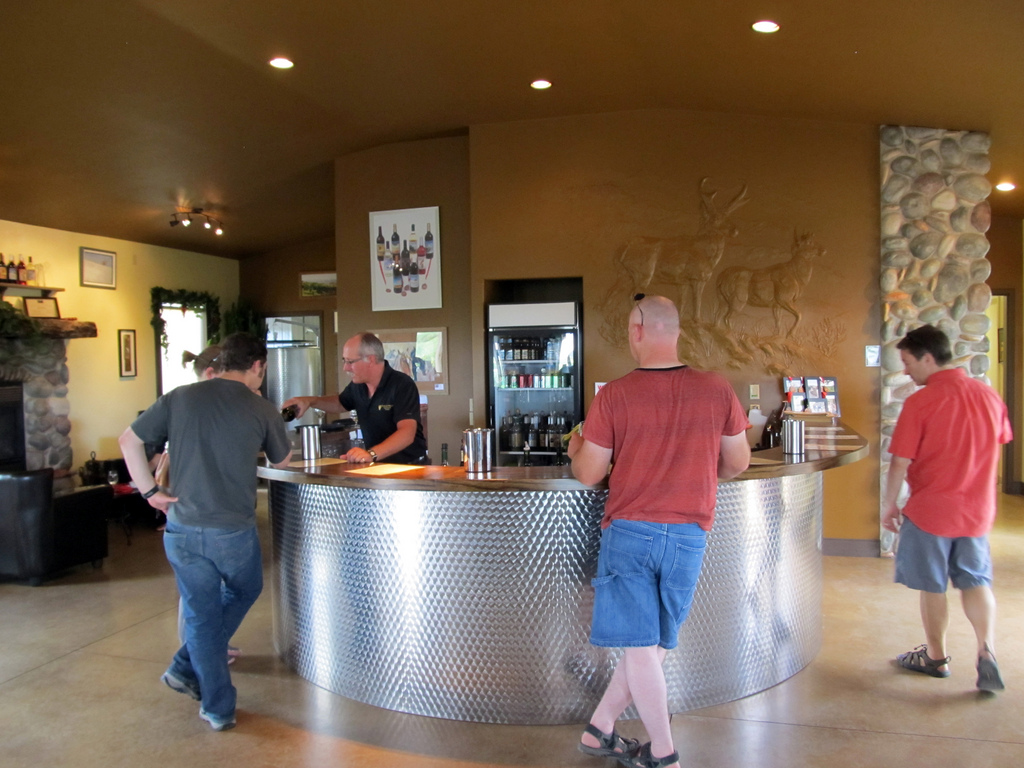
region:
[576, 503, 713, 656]
Man wearing shorts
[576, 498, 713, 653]
Man is wearing shorts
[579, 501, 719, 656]
Man wearing blue shorts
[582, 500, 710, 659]
Man wearing jean shorts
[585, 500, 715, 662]
Man is wearing jean shorts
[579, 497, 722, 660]
Man wearing blue jean shorts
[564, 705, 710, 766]
Man wearing sandals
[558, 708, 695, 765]
Man is wearing sandals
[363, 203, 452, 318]
framed artwork on a wall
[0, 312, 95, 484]
stone and mortar fireplace with wooden mantel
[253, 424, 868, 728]
horseshoe shaped metal bar with wooden counter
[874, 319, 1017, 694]
man wearing sandals, shorts and a shortsleeved red shirt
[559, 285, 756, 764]
man with sunglasses on his head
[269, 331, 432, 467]
bartender with glasses pouring a drink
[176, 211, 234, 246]
ceiling lighting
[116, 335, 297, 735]
man wearing sneakers, jeans and a short sleeved tee shirt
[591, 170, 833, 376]
frieze of deer on a wall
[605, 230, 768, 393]
the head of a man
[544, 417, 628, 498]
the elbow of a man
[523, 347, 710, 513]
the arm of a man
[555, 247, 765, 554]
the back of a man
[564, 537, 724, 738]
the legs of a man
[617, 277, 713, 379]
the hair of a man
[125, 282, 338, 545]
a man wearing a shirt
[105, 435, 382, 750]
a man wearing pants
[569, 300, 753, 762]
A bald man standing at a desk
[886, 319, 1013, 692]
A man in a red shirt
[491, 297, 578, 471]
A beverage refrigerated container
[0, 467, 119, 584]
A black chair by the fireplace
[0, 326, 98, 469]
A stone brick fireplace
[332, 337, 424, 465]
The bartender behind the bar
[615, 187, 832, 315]
A deer drawing on the wall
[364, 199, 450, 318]
A painting on the wall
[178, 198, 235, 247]
A light figure on the ceiling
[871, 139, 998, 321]
A stone brick wall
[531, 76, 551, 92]
a light on the ceiling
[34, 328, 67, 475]
rocks on the wall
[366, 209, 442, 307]
a picture on the wall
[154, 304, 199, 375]
the door way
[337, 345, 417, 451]
a man in a black shirt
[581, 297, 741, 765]
a man in a red shirt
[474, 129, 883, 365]
a brown wall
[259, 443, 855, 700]
a bar counter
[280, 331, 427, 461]
a man pouring a drink